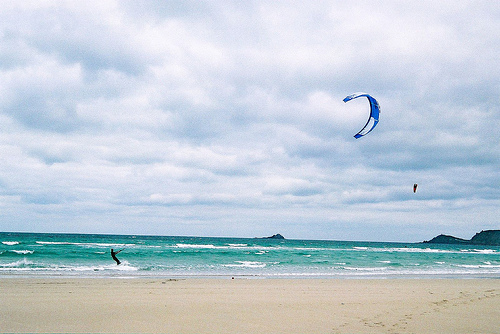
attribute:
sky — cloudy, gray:
[0, 1, 499, 244]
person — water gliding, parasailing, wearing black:
[110, 245, 127, 264]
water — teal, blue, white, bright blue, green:
[0, 231, 500, 278]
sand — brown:
[0, 276, 499, 334]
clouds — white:
[0, 1, 499, 232]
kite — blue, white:
[343, 91, 381, 138]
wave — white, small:
[0, 238, 499, 271]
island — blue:
[262, 233, 285, 239]